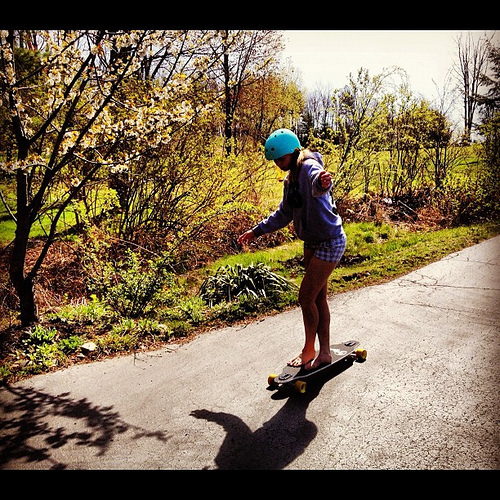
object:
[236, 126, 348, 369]
girl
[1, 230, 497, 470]
sidewalk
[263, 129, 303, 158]
helmet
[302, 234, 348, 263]
shorts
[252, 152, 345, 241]
hoodie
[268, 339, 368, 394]
skateboard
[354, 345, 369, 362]
wheel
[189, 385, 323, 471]
shadow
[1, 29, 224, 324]
tree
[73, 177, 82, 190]
blossom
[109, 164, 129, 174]
blossom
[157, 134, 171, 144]
blossom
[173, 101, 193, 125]
blossom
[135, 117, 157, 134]
blossom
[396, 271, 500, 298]
cracks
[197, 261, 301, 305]
plant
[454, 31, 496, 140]
tree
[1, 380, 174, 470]
shadow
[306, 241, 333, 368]
leg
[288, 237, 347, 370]
leg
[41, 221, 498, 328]
grass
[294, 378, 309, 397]
wheel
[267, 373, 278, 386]
wheel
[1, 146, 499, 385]
field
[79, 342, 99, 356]
rock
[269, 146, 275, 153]
hole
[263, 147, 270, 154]
hole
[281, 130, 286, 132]
hole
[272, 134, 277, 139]
hole